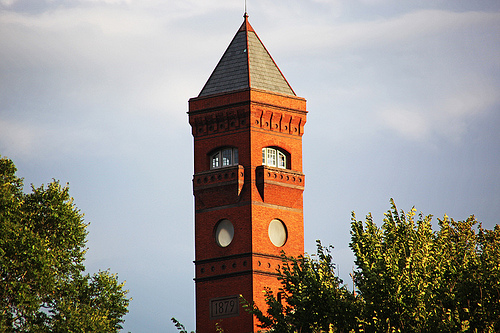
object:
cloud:
[0, 0, 500, 333]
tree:
[2, 157, 132, 331]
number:
[215, 300, 236, 314]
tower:
[188, 3, 308, 333]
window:
[210, 145, 240, 170]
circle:
[268, 218, 289, 248]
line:
[195, 201, 302, 213]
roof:
[184, 15, 306, 104]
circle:
[213, 217, 235, 247]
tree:
[241, 186, 499, 333]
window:
[260, 146, 290, 170]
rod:
[244, 0, 247, 18]